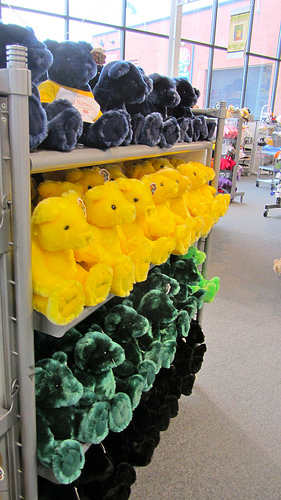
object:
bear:
[41, 38, 130, 154]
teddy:
[82, 184, 150, 299]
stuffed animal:
[104, 299, 156, 412]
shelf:
[0, 42, 228, 500]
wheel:
[263, 212, 267, 217]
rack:
[227, 108, 253, 204]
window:
[171, 41, 210, 109]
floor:
[132, 170, 277, 500]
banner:
[227, 11, 250, 54]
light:
[111, 39, 115, 45]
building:
[92, 1, 281, 148]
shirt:
[37, 79, 103, 123]